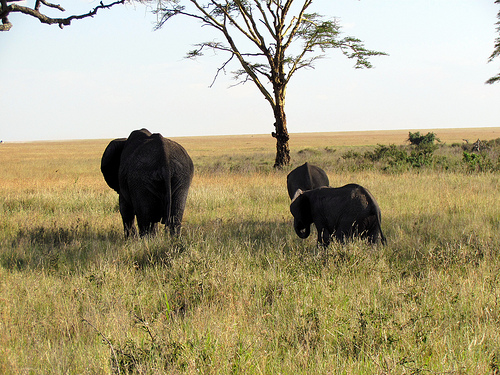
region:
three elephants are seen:
[95, 125, 418, 275]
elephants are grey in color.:
[85, 130, 406, 295]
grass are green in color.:
[150, 275, 475, 360]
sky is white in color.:
[20, 50, 170, 100]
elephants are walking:
[105, 110, 417, 237]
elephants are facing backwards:
[131, 142, 387, 232]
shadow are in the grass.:
[51, 195, 487, 300]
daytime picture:
[51, 55, 471, 340]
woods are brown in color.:
[225, 40, 305, 155]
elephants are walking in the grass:
[102, 129, 394, 264]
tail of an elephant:
[162, 153, 179, 220]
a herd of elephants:
[101, 129, 386, 269]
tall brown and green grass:
[213, 254, 318, 336]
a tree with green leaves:
[253, 10, 375, 117]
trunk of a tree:
[271, 112, 292, 158]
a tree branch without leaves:
[25, 2, 125, 31]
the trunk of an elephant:
[290, 222, 317, 237]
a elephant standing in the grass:
[286, 182, 393, 248]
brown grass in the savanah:
[305, 133, 401, 166]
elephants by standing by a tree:
[88, 75, 423, 266]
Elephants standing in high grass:
[97, 130, 395, 252]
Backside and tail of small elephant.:
[282, 162, 324, 189]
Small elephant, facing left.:
[290, 185, 390, 250]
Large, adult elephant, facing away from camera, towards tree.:
[100, 125, 192, 237]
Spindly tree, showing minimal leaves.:
[162, 3, 353, 170]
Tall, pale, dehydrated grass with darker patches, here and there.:
[46, 241, 487, 363]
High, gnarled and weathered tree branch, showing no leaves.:
[0, 4, 138, 36]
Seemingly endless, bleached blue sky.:
[10, 0, 496, 129]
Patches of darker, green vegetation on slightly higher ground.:
[321, 129, 498, 178]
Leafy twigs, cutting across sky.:
[483, 3, 498, 92]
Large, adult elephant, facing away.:
[102, 122, 207, 255]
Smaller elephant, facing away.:
[284, 161, 334, 190]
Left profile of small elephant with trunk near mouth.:
[289, 185, 391, 260]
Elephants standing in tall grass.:
[104, 122, 399, 265]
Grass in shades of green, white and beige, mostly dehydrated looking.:
[14, 137, 499, 372]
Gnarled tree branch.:
[1, 0, 133, 55]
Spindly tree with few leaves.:
[161, 5, 345, 165]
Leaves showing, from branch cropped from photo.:
[479, 0, 489, 96]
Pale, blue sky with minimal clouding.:
[31, 37, 272, 122]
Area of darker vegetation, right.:
[366, 128, 498, 184]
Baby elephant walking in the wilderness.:
[288, 173, 384, 254]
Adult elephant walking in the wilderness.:
[100, 125, 211, 280]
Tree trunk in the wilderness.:
[230, 105, 301, 160]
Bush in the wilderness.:
[405, 130, 450, 151]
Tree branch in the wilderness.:
[251, 82, 266, 107]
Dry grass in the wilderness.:
[90, 255, 270, 355]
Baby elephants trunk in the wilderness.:
[291, 225, 311, 240]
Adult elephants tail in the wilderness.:
[146, 175, 186, 220]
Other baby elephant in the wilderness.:
[285, 165, 330, 190]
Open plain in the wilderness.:
[22, 140, 95, 177]